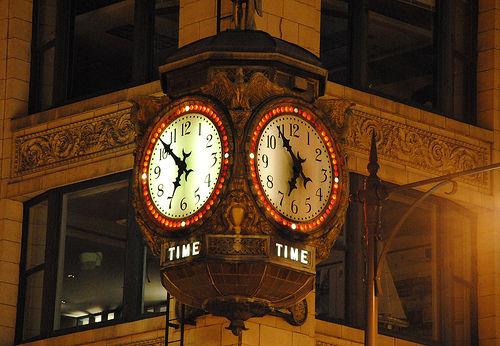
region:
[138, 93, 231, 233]
The clock on the left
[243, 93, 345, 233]
The clock on thr right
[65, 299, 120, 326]
The light coming through the windows in the building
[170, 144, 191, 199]
The hour hand on the left clock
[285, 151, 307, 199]
The hour hand on the right clock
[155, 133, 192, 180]
The minute hand on the left clock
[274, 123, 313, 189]
The minute hand on the right clock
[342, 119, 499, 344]
The light pole on the right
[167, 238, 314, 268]
The illuminated words below the clocks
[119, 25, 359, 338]
The large structure the clocks are on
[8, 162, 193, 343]
Windows are in the building.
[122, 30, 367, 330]
The clock is hanging off of a building.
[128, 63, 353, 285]
The clock is lit up.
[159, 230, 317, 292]
The clock says time.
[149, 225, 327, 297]
The letters time are lit up.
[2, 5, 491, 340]
The building is brown.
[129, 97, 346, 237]
The clock face is white.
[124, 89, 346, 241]
The clock face has an orange ring around it.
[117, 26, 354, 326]
The clock is large.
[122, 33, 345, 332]
The clock case is brown.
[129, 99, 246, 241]
clock that say 6:52pm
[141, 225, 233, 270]
sign saying time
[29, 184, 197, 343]
window of a building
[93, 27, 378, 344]
clock hanging from the ceiling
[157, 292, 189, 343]
latter to top of building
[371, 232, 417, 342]
sail boat in the window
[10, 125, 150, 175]
building with decorative design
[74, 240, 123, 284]
fire alarm in building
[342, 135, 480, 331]
sign holder next to building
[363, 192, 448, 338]
boat in the lower window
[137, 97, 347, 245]
A hanging clock.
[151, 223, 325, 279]
The word time is lit up.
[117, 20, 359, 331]
The clock is hanging on a building.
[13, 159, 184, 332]
The building has windows.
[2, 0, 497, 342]
A building is in the background.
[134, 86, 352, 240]
The clock has and orange ring around it.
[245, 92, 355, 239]
round clock face with lights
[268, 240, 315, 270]
lit up time on a clock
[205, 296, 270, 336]
ornate finial on a clock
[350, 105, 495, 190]
fancy stone carving on the wall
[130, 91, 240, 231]
clock that reads 6:52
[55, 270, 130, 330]
empty office with safety lights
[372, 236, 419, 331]
sailboat in the window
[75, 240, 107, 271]
light fixture in an office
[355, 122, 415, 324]
ornate pointy spear atop a street light post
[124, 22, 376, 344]
multi-faced clock outside a building